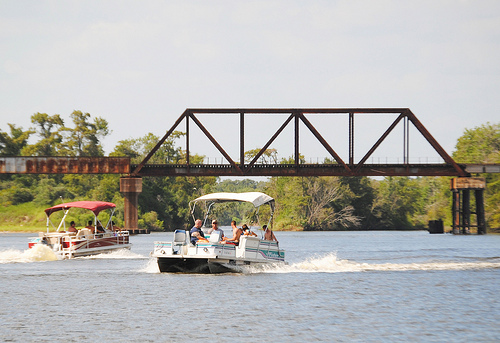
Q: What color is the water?
A: Brown.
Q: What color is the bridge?
A: Dark, rustic brown.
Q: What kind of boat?
A: Pontoon.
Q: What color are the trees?
A: Green.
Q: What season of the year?
A: Summer.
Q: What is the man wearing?
A: Swim trunks and no shirt.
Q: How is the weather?
A: Clear.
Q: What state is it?
A: Wisconsin.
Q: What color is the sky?
A: Gray.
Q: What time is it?
A: Afternoon.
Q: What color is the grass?
A: Green.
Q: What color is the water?
A: Blue.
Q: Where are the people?
A: In the boat.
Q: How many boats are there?
A: Two.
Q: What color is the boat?
A: White and red.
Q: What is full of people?
A: Boat.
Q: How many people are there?
A: More than five.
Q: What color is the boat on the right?
A: Blue and white.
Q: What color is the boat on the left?
A: Red and white.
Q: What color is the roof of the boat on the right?
A: White.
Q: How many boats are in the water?
A: 2.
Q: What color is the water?
A: Light blue.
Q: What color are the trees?
A: Green.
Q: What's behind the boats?
A: A bridge.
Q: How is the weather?
A: Sunny.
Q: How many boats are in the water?
A: Two.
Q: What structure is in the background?
A: A bridge.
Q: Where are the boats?
A: On the water.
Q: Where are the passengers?
A: Riding on boats.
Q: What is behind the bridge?
A: Trees.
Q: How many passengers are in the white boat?
A: Five.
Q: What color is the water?
A: Blue grey.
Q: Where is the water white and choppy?
A: Under the boats.